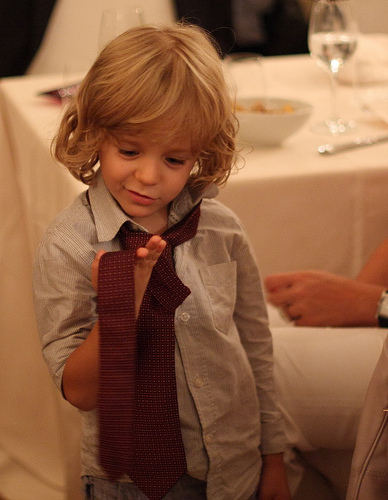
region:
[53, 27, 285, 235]
Little boy with long hair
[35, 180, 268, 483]
little boy with red tie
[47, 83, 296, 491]
Little boy looking at his tie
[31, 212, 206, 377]
boy holding a tie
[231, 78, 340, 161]
white bowl of food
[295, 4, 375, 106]
wine glass of water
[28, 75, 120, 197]
blonde curly hair on boy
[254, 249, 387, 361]
hand on lap with watch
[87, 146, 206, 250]
Little boy smirking at hand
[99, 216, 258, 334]
untied red tie on boy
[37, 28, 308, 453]
Little boy holds tie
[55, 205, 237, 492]
tie is red with dots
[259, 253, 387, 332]
someone wears a watch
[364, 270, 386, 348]
Watch has black band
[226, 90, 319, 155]
White bowl on table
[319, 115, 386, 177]
Knife on the table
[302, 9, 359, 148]
A half full glass of water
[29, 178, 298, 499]
The boy wears a brown shirt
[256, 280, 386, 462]
The person wears white pants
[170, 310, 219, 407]
White buttons on boy's shirt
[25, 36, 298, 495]
Young boy wearing a tie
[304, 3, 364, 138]
Glass of water on the table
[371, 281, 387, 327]
The watch on the wrist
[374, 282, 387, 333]
The watch is black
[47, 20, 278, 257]
The boy has long blonde hair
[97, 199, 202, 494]
The tie is burgundy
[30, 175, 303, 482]
The boy wearing a gray shirt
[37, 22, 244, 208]
The boy has curly hair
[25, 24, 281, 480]
The boy is looking at the tie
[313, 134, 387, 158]
The silverware on the table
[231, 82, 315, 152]
white bowl on round table.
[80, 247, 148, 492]
Red tie in boy's hand.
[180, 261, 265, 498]
Boy is wearing a grey shirt.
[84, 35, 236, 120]
Dirty blonde hair on top of boy's head.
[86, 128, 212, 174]
Boy's eyes are looking down.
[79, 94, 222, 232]
Boy has a smile on his face.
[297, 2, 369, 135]
Silver wine glass with wine.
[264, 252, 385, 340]
Man's hand is on table.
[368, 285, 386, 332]
Black wrist watch on man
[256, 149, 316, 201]
Peach table cloth on table.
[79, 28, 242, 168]
blond haired kid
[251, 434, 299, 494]
wrist of the kid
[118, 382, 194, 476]
red tie on kid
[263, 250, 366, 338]
hand of an adult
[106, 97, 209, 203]
kid looking at tie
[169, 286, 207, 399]
buttons on shirt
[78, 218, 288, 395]
long sleeved shirt on kid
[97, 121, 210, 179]
two eyes of the kid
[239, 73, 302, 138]
bowl on table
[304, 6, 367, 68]
clear glass with liquid in it